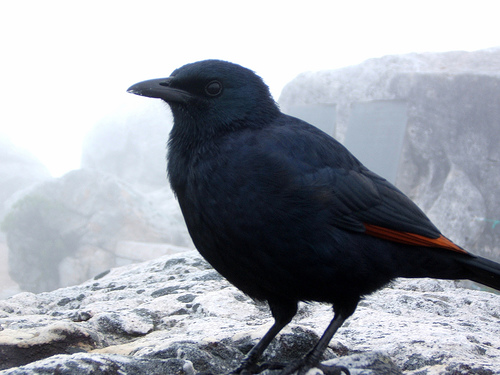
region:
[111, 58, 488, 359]
a black bird standing on a rock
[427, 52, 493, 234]
grey craggy surface of the mountain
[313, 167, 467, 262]
red and black feathered wings of the bird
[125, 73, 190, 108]
black beak of the bird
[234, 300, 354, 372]
black legs of the bird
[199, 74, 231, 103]
black eye of the bird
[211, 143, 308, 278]
black feathered belly of the bird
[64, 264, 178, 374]
grey surface of the rock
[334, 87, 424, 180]
smooth carved surface of the rock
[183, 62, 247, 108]
bird has beady eye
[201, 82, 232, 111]
birds eye is black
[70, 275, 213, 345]
ground is rocky and snowy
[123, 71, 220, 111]
bird has black beak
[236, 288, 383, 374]
bird has 2 feet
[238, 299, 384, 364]
birds legs are black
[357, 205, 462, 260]
a single red feather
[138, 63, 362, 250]
the bird looks fluffy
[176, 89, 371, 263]
bird is blue/black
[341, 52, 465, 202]
foggy and rocks in back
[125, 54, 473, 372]
A small black bird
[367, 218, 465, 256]
Red feathers on a blackbird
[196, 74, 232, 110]
eye of a bird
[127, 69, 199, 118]
This is a bird's beak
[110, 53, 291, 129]
The head of a black bird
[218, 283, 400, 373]
The legs of a blackbird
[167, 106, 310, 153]
The neck of a black bird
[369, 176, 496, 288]
That tail feathers of a black bird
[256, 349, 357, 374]
The left claw of a blackbird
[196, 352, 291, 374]
The right claw of a blackbird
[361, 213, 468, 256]
small section of red bird feathers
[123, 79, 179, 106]
one pointy black bird beak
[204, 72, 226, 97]
one round black bird eye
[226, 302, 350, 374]
two thin black bird legs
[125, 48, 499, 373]
one black bird with black legs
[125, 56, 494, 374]
one small dark bird standing on rocks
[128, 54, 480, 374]
black bird on light colored rocks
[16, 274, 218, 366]
spotted light colored craggy rocks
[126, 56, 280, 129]
one black bird head in profile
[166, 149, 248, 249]
one black bird chest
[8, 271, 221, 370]
The rocks on the mountain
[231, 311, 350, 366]
The legs of the bird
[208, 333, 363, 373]
The feet of the bird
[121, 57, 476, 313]
The bird is the color black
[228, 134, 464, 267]
The wing of the bird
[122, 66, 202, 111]
The beak of the bird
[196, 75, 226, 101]
The eye of the bird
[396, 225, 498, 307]
The tail of the bird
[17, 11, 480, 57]
The sky is clear and bright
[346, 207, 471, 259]
The bird has orange on it